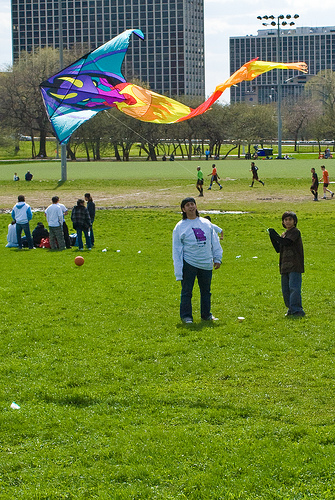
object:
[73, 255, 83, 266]
basketball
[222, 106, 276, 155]
buds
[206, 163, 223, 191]
man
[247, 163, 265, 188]
man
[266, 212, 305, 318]
boy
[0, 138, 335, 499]
field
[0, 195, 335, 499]
grass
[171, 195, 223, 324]
people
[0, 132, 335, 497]
park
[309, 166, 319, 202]
people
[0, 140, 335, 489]
grass in park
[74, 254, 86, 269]
rolling on ground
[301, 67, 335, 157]
tree with light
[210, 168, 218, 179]
orange tee shirt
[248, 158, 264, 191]
man running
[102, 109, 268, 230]
extended kite string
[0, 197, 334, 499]
grass in the field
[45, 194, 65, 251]
standing in a park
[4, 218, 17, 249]
children sitting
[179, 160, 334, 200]
people playing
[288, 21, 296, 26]
stadium lights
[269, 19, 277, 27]
stadium lights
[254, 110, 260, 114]
trees with leaves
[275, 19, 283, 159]
large light pole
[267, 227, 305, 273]
sleeve sweater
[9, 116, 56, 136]
branch of a tree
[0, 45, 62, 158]
tall green tree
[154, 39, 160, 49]
window of a building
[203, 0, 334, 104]
white cloud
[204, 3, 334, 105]
blue sky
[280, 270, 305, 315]
blue jean pants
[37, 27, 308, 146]
flying in sky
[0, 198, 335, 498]
field of grass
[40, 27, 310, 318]
boy is flying kite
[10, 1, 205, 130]
tall buildings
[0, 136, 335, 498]
ground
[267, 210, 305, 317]
watching boy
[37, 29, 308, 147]
colorful kite flying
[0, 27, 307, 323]
enjoying the park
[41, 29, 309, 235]
kite flying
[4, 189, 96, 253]
on the grass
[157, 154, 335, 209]
people playing ball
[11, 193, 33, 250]
people relaxing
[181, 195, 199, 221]
dark hair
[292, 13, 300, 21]
stadium lights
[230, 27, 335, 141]
office building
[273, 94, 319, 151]
trees along roadside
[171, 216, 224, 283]
white hoodie